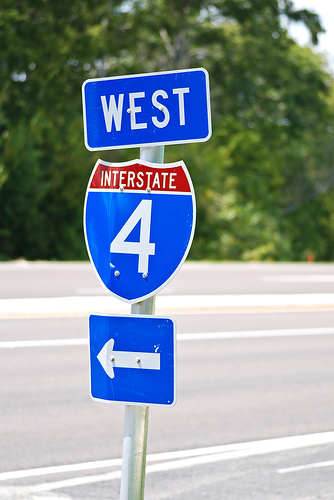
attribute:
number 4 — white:
[109, 198, 155, 275]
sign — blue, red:
[71, 82, 193, 259]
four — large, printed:
[85, 159, 206, 302]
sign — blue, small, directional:
[82, 312, 178, 407]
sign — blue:
[47, 51, 231, 420]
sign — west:
[65, 66, 229, 156]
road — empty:
[186, 303, 325, 414]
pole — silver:
[102, 411, 169, 498]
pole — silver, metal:
[122, 407, 143, 498]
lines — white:
[0, 427, 333, 495]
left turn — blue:
[91, 317, 179, 403]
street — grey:
[3, 260, 331, 498]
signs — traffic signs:
[78, 68, 210, 152]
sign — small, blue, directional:
[77, 71, 215, 150]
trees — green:
[225, 31, 311, 245]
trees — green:
[28, 32, 83, 239]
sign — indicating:
[67, 133, 221, 286]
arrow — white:
[84, 328, 179, 404]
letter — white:
[98, 93, 123, 133]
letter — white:
[127, 88, 148, 130]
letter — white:
[149, 88, 169, 129]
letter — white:
[171, 85, 189, 126]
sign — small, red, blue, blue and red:
[82, 158, 195, 304]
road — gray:
[7, 266, 326, 495]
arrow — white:
[97, 335, 162, 376]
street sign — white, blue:
[81, 66, 212, 151]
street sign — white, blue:
[83, 157, 198, 305]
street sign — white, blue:
[87, 312, 175, 409]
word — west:
[98, 85, 189, 134]